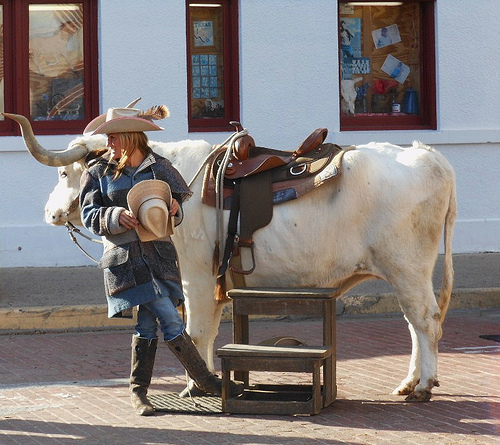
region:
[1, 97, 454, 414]
cowgirl standing in front of a white steer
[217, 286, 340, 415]
old rickety step stool made of wood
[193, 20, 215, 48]
blue and white sign that says Texas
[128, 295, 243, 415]
blue denim jeans tucked into brown cowboy boots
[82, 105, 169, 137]
pink and tan cowboy hat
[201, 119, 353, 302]
brown leather saddle with metal stirrup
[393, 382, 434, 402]
brownish gray rear hooves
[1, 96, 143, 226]
sharp looking horns on the steer's head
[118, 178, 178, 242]
cowboy hat being held in her hands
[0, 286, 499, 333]
chipped and dirty yellow painted curb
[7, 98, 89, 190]
large horn of bull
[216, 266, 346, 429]
wooden steps on ground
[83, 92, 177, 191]
girl wearing cowboy hat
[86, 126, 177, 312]
girl wearing long coat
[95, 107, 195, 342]
girl wearing blue jeans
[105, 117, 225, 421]
girl wearing long boots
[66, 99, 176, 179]
girl standing with blonde hair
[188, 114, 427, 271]
bull with a saddle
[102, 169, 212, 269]
girl holding cowboy hat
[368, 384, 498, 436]
shadow of bull on ground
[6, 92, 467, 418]
A white bull in the middle of a road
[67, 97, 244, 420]
A lady leaning against a white bull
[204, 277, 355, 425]
Wooden steps to mount the bull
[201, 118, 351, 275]
Leather saddle on the bull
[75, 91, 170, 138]
A cowboy hat with a feather on it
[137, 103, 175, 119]
A feather sticking out of a cowboy hat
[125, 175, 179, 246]
A cowboy hat being held by a lady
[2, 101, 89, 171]
The horn of a bull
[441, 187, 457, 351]
The tail of a bull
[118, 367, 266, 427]
A sewer grate in the middle of the road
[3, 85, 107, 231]
Bull face with horns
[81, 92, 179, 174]
Lady with cowboy hat on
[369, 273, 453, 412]
Hind bull legs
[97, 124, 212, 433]
Woman wearing cowboy boots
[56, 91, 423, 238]
Saddle on a bull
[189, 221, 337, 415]
Wooden steps to climb on bull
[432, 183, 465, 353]
Bull's tail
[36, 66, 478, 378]
Woman and bull posing together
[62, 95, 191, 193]
Blonde woman wearing cowboy hat with feather in it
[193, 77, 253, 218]
Rope on a saddle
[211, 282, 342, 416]
Steps for mounting a bull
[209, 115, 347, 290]
Saddle on a bull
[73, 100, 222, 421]
Someone holding a cowbody hat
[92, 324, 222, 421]
Tall boots on a persons feet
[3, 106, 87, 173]
Horn on a bull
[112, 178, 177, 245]
Cowboy hat in someones hands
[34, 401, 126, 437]
Brick covered street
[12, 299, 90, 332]
Yellow curb beside street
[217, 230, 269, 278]
Stirrup on a saddle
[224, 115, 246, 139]
Saddlehorn on a saddle